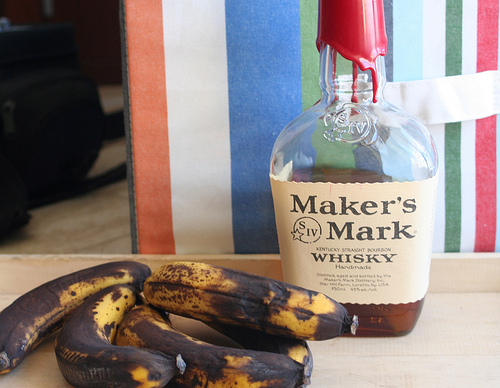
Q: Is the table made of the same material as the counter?
A: Yes, both the table and the counter are made of wood.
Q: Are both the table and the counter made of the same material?
A: Yes, both the table and the counter are made of wood.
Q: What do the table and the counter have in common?
A: The material, both the table and the counter are wooden.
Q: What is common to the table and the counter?
A: The material, both the table and the counter are wooden.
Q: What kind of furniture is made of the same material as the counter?
A: The table is made of the same material as the counter.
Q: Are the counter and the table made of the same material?
A: Yes, both the counter and the table are made of wood.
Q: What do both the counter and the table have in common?
A: The material, both the counter and the table are wooden.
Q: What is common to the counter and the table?
A: The material, both the counter and the table are wooden.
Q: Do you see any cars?
A: No, there are no cars.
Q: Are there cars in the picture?
A: No, there are no cars.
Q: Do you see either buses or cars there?
A: No, there are no cars or buses.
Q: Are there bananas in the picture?
A: Yes, there is a banana.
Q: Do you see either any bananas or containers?
A: Yes, there is a banana.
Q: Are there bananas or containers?
A: Yes, there is a banana.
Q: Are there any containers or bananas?
A: Yes, there is a banana.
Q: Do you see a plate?
A: No, there are no plates.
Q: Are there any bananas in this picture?
A: Yes, there are bananas.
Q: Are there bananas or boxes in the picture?
A: Yes, there are bananas.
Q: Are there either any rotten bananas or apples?
A: Yes, there are rotten bananas.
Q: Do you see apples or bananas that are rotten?
A: Yes, the bananas are rotten.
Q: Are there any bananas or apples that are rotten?
A: Yes, the bananas are rotten.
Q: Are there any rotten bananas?
A: Yes, there are rotten bananas.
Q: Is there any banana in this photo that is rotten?
A: Yes, there are bananas that are rotten.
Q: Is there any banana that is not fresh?
A: Yes, there are rotten bananas.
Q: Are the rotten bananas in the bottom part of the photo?
A: Yes, the bananas are in the bottom of the image.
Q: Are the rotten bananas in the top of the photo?
A: No, the bananas are in the bottom of the image.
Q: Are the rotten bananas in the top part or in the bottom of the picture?
A: The bananas are in the bottom of the image.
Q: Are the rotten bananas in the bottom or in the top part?
A: The bananas are in the bottom of the image.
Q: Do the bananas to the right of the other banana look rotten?
A: Yes, the bananas are rotten.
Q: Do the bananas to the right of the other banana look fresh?
A: No, the bananas are rotten.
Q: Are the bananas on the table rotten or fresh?
A: The bananas are rotten.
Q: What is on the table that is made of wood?
A: The bananas are on the table.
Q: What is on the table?
A: The bananas are on the table.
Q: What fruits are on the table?
A: The fruits are bananas.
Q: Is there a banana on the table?
A: Yes, there are bananas on the table.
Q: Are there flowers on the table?
A: No, there are bananas on the table.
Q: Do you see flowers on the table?
A: No, there are bananas on the table.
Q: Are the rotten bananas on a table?
A: Yes, the bananas are on a table.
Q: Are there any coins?
A: No, there are no coins.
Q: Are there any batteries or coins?
A: No, there are no coins or batteries.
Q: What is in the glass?
A: The liquid is in the glass.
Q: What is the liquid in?
A: The liquid is in the glass.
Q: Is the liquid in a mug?
A: No, the liquid is in the glass.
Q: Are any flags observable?
A: No, there are no flags.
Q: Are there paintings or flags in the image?
A: No, there are no flags or paintings.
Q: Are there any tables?
A: Yes, there is a table.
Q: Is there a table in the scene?
A: Yes, there is a table.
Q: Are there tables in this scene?
A: Yes, there is a table.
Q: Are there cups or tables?
A: Yes, there is a table.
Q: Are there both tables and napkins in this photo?
A: No, there is a table but no napkins.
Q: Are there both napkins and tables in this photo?
A: No, there is a table but no napkins.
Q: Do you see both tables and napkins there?
A: No, there is a table but no napkins.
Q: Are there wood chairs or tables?
A: Yes, there is a wood table.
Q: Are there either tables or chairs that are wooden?
A: Yes, the table is wooden.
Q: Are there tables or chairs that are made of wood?
A: Yes, the table is made of wood.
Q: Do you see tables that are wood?
A: Yes, there is a wood table.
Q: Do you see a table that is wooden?
A: Yes, there is a table that is wooden.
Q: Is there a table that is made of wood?
A: Yes, there is a table that is made of wood.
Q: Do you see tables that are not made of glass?
A: Yes, there is a table that is made of wood.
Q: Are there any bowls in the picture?
A: No, there are no bowls.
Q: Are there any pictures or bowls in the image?
A: No, there are no bowls or pictures.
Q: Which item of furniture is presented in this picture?
A: The piece of furniture is a table.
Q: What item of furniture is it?
A: The piece of furniture is a table.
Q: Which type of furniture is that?
A: That is a table.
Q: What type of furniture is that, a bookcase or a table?
A: That is a table.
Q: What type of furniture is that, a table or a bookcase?
A: That is a table.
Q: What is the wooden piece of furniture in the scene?
A: The piece of furniture is a table.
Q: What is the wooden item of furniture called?
A: The piece of furniture is a table.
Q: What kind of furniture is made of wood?
A: The furniture is a table.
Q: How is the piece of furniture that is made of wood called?
A: The piece of furniture is a table.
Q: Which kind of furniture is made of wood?
A: The furniture is a table.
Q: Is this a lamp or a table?
A: This is a table.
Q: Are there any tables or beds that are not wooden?
A: No, there is a table but it is wooden.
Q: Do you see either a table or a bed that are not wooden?
A: No, there is a table but it is wooden.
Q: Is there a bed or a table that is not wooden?
A: No, there is a table but it is wooden.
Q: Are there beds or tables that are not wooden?
A: No, there is a table but it is wooden.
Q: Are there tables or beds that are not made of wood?
A: No, there is a table but it is made of wood.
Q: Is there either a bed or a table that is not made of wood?
A: No, there is a table but it is made of wood.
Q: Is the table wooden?
A: Yes, the table is wooden.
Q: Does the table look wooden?
A: Yes, the table is wooden.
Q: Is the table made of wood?
A: Yes, the table is made of wood.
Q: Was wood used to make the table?
A: Yes, the table is made of wood.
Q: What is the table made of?
A: The table is made of wood.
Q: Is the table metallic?
A: No, the table is wooden.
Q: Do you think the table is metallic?
A: No, the table is wooden.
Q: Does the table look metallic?
A: No, the table is wooden.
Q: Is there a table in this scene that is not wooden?
A: No, there is a table but it is wooden.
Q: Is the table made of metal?
A: No, the table is made of wood.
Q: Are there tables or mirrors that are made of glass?
A: No, there is a table but it is made of wood.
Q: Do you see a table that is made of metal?
A: No, there is a table but it is made of wood.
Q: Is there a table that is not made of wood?
A: No, there is a table but it is made of wood.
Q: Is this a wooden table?
A: Yes, this is a wooden table.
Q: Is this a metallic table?
A: No, this is a wooden table.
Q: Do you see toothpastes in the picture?
A: No, there are no toothpastes.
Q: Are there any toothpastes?
A: No, there are no toothpastes.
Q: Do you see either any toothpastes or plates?
A: No, there are no toothpastes or plates.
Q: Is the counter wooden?
A: Yes, the counter is wooden.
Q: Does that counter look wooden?
A: Yes, the counter is wooden.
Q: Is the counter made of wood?
A: Yes, the counter is made of wood.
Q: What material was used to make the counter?
A: The counter is made of wood.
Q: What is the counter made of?
A: The counter is made of wood.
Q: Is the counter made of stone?
A: No, the counter is made of wood.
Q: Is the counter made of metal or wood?
A: The counter is made of wood.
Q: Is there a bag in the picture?
A: Yes, there is a bag.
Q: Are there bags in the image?
A: Yes, there is a bag.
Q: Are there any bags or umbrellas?
A: Yes, there is a bag.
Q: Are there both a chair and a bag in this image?
A: No, there is a bag but no chairs.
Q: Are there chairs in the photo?
A: No, there are no chairs.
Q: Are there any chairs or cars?
A: No, there are no chairs or cars.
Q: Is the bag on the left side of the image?
A: Yes, the bag is on the left of the image.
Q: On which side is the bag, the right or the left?
A: The bag is on the left of the image.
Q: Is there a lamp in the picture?
A: No, there are no lamps.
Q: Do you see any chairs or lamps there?
A: No, there are no lamps or chairs.